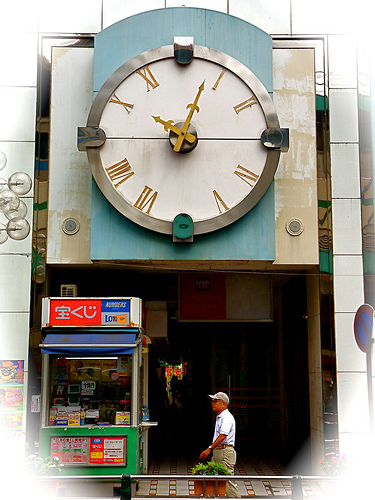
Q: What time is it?
A: 10:03.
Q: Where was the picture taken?
A: In a market area.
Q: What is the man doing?
A: Standing.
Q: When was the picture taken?
A: In the daytime.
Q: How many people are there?
A: 1.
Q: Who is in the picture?
A: A man.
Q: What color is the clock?
A: White and Silver.